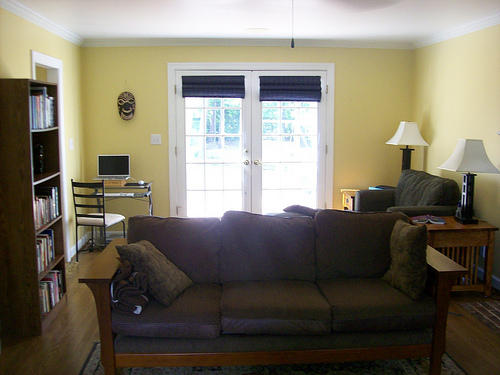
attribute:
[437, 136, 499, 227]
lamp — black, white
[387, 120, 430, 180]
lamp — black, white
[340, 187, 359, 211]
table — wooden, brown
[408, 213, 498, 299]
table — brown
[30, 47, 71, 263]
frame — white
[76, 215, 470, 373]
couch — brown, gray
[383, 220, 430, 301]
pillow — brown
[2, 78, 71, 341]
bookcase — wooden, brown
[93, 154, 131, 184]
computer — silver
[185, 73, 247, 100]
shade — black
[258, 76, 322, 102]
shade — black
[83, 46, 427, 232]
wall — yellow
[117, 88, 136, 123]
mask — hanging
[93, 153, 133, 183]
laptop — here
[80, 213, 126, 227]
cushion — light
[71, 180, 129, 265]
chair — dark, black, white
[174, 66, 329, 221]
doors — white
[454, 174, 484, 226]
lamp — black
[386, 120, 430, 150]
shade — white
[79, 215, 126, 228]
seat — white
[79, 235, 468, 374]
frame — wood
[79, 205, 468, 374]
sofa — gray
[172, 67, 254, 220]
door — white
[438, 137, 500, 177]
shade — white